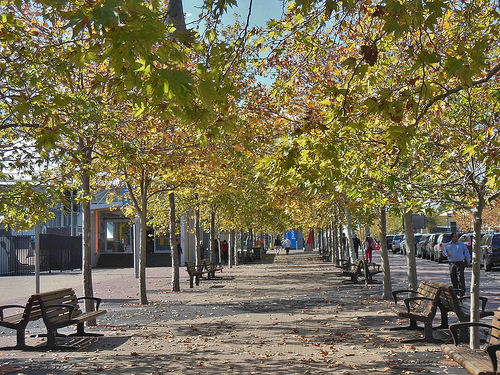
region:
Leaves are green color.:
[55, 38, 368, 147]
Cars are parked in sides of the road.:
[381, 228, 493, 263]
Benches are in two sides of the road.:
[24, 246, 496, 374]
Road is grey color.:
[114, 306, 201, 326]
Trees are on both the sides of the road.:
[38, 139, 494, 339]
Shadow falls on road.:
[15, 262, 472, 361]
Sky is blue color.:
[192, 1, 297, 36]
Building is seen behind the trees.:
[8, 171, 194, 283]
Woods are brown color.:
[78, 211, 97, 299]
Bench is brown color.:
[21, 288, 84, 332]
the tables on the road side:
[38, 285, 111, 347]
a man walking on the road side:
[431, 219, 472, 311]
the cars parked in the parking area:
[410, 222, 485, 267]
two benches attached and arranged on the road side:
[377, 267, 492, 345]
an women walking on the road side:
[359, 228, 386, 283]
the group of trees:
[44, 73, 266, 318]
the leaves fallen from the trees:
[131, 318, 253, 369]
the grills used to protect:
[8, 225, 85, 274]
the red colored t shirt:
[215, 237, 237, 269]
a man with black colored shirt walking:
[267, 235, 284, 255]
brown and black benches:
[9, 270, 108, 342]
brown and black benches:
[379, 267, 444, 335]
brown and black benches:
[178, 250, 239, 290]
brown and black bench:
[325, 247, 364, 293]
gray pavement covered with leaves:
[241, 275, 339, 370]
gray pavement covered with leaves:
[148, 295, 264, 365]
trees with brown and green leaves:
[21, 15, 181, 276]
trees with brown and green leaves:
[139, 18, 299, 239]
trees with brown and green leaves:
[240, 3, 405, 235]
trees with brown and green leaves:
[361, 9, 491, 231]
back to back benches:
[0, 268, 107, 344]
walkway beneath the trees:
[100, 32, 438, 341]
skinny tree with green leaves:
[18, 0, 142, 302]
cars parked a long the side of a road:
[369, 216, 491, 282]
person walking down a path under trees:
[261, 157, 322, 308]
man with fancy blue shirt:
[431, 222, 482, 307]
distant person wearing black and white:
[281, 233, 296, 256]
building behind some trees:
[1, 121, 249, 281]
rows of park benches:
[13, 227, 470, 346]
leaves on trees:
[157, 48, 413, 199]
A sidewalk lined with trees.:
[18, 18, 492, 358]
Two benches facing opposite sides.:
[5, 275, 105, 345]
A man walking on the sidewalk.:
[435, 230, 475, 310]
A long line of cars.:
[370, 215, 495, 275]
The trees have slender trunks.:
[45, 40, 165, 310]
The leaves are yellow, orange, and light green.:
[20, 20, 490, 250]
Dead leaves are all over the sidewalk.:
[105, 270, 425, 370]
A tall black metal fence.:
[0, 220, 85, 275]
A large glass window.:
[100, 215, 130, 250]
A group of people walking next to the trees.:
[335, 227, 380, 264]